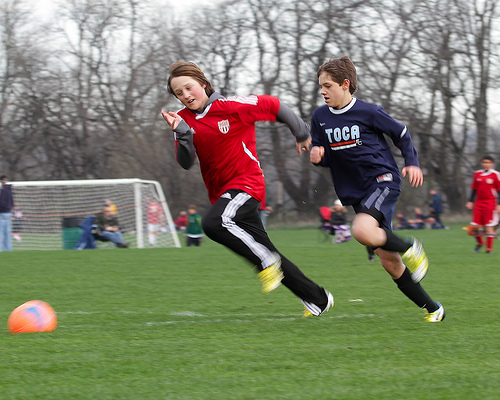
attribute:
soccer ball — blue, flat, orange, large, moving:
[8, 298, 56, 336]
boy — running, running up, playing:
[159, 60, 335, 319]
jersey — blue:
[311, 96, 419, 205]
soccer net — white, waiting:
[1, 176, 182, 248]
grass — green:
[0, 227, 499, 396]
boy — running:
[308, 56, 446, 323]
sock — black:
[392, 266, 439, 311]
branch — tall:
[248, 1, 267, 82]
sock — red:
[477, 232, 482, 249]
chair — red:
[318, 207, 332, 239]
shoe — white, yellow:
[260, 250, 284, 293]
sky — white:
[2, 2, 500, 132]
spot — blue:
[26, 307, 40, 318]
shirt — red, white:
[175, 94, 279, 208]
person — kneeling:
[187, 202, 204, 246]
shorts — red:
[471, 207, 497, 226]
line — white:
[0, 308, 374, 328]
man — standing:
[0, 176, 17, 251]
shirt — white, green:
[186, 214, 203, 236]